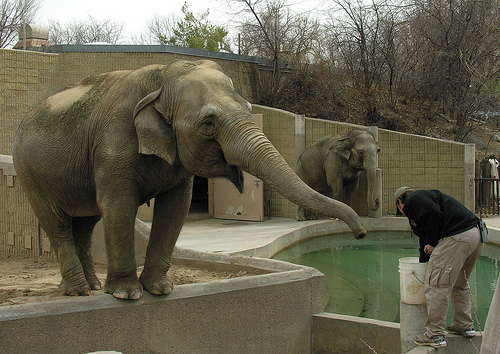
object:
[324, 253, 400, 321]
stairs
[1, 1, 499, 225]
background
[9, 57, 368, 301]
elephant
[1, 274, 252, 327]
ledge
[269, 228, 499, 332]
water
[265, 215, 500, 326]
pool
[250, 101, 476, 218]
wall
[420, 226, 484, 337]
pants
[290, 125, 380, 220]
elephant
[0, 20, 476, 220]
building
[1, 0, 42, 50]
tree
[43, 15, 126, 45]
tree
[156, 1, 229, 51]
tree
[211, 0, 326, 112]
tree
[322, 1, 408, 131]
tree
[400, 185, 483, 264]
sweatshirt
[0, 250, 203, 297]
dirt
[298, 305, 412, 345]
cement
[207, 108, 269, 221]
door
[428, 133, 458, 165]
brick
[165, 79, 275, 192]
face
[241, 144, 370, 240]
trunk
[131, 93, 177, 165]
ear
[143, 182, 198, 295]
left leg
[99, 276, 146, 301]
toes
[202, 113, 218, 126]
right eye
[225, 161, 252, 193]
mouth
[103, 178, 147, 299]
front legs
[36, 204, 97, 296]
back legs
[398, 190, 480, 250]
black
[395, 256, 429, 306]
bucket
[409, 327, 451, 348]
sneakers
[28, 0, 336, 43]
sky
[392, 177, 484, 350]
man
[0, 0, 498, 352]
zoo